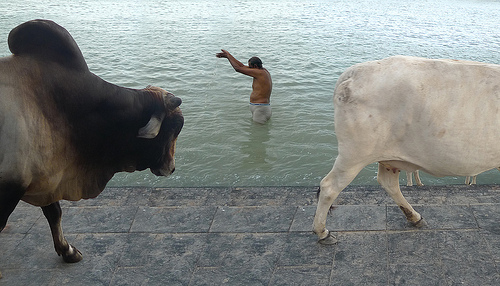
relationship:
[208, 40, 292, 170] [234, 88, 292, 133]
man wearing underware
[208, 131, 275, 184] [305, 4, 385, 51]
ripples of water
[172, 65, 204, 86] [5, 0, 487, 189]
ripples in water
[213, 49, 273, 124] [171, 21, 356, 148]
man in water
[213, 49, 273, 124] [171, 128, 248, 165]
man in a water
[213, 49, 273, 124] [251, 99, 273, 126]
man wearing underwear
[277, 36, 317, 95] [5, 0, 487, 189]
ripples in water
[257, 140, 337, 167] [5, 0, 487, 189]
ripples in water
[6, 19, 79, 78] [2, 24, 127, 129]
hump on animals back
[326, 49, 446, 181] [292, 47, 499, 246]
rear of animal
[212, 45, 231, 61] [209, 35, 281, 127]
hands of man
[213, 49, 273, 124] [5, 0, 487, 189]
man in water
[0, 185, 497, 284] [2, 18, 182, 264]
ground under animal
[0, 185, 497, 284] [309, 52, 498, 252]
ground under animal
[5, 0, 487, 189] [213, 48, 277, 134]
water under man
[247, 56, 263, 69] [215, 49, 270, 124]
head of man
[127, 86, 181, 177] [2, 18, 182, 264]
head of animal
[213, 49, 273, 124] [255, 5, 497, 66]
man in water